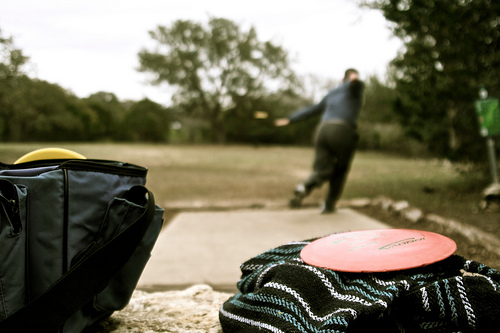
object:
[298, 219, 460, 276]
frisbee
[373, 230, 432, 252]
lettering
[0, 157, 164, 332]
bag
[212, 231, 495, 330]
pullover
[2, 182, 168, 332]
strap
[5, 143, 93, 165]
frisbee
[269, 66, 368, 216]
man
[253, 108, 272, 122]
frisbee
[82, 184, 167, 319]
pocket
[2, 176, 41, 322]
pocket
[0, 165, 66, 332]
back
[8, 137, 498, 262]
field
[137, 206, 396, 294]
slab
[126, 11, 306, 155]
tree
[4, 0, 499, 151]
background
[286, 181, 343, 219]
feet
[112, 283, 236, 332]
rock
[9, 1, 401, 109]
sky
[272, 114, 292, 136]
hand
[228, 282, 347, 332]
stripes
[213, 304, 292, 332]
stripe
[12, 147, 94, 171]
edge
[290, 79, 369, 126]
shirt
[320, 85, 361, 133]
torso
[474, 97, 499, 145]
sign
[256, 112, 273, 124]
thrown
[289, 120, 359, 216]
trouser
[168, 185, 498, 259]
line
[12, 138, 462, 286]
sporting equipment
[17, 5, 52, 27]
part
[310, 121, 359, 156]
part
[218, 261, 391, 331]
hood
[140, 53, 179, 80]
leaves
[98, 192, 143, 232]
part